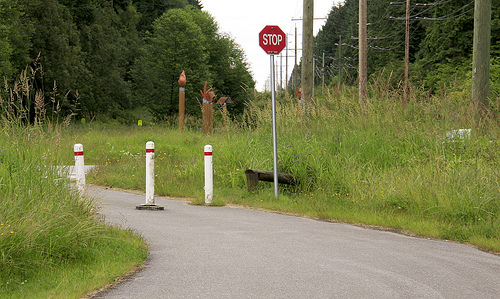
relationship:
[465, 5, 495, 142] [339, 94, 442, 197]
pole in grass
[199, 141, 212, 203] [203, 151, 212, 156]
pole with red stripe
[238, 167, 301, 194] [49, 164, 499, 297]
broken post on road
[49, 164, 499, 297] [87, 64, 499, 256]
road through grass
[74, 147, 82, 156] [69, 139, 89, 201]
stripe on pole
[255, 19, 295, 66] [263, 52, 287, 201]
stop sign on pole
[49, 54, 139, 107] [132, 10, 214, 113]
leaves on tree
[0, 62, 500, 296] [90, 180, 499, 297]
grass on road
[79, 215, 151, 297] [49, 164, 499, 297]
road edge on road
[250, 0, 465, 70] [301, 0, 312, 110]
electrical lines on pole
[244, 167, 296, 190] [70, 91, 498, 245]
broken post in grass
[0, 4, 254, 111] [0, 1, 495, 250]
trees in forest